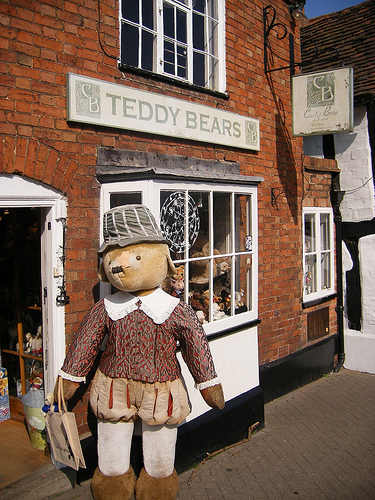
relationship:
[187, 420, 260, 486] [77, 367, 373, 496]
stick on sidewalk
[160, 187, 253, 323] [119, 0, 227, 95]
window upright window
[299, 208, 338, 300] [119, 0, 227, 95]
window upright window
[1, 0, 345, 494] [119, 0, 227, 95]
store upright window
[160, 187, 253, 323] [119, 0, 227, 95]
window closed window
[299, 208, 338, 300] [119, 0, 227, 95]
window closed window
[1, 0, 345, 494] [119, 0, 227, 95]
store see through window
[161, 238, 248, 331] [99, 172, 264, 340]
teddy bears in window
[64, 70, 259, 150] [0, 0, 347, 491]
sign on building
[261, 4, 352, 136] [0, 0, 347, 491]
sign on building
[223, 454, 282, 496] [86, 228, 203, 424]
ground under bear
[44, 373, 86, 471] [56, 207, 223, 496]
bag on bear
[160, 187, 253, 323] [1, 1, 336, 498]
window on place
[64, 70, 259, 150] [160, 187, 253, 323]
sign above window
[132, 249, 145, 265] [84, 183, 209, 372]
eye on bear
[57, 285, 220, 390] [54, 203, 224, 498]
shirt on teddy bear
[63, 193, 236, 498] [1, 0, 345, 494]
teddy bear at store